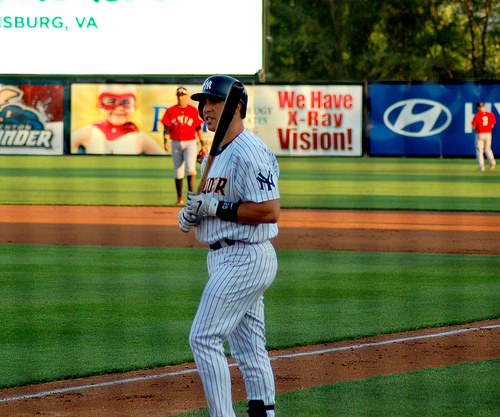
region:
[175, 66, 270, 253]
wooden base ball bat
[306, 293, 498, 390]
white lines painted on baseball field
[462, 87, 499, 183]
outfielder in red uniform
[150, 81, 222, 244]
outfielder in red baseball uniform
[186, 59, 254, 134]
hard dark nlue safety batters helmet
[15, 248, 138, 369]
bright green infield grass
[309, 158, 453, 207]
bright green outfield grass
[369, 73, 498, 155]
blue and white advertising banners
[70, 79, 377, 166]
multicolored advertising banner in baby on it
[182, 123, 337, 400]
white baseball uniform with blue stripes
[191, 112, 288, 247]
man wears pinstriped shirt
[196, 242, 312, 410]
man wears pinstriped pants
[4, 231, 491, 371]
infield is dark green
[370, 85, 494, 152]
right wall is blue and white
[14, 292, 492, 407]
painted line on infield dirt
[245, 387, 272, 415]
man wears shin guard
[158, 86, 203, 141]
opposing infielder wears red shirt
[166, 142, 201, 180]
opposing infielder wears grey pants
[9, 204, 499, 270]
infield dirt is clay brown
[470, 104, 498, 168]
opposing outfielder is turned away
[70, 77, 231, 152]
The billboard sign with the little boy on it.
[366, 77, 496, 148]
The blue and white billboard sign.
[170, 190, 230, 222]
The gloves the batter is wearing.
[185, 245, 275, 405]
The pants the batter is wearing.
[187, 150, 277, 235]
The shirt the batter is wearing.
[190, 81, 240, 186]
The bat the batter is holding.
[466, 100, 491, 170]
The player in front of the blue and white billboard sign.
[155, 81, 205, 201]
The player in front of the billboard with the little boy on it.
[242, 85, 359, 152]
The billboard sign that has the word Vision on it.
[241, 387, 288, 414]
The ankle support on the batter's leg area.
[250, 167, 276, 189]
The New York Yankee sign on the batter's sleeve.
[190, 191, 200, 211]
The Nike emblem on the batter's glove.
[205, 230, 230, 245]
The belt on the batter's pants.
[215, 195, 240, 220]
The black sweatband onthe batter's wrist.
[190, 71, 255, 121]
The black helmet the batter is wearing.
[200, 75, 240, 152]
The tip of the black bat the batter is holding.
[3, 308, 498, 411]
The white line on the field.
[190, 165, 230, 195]
The gold and brown letters on the front of the batter's shirt.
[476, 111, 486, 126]
The number 3 on the player's shirt next to the blue sign.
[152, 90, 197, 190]
The player standing in the field facing the batter.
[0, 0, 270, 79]
white board in the background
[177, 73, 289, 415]
baseball player wearing white shirt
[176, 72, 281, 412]
baseball player holding black ball and bat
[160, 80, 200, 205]
baseball player wearing red shirt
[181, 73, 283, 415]
baseball player wearing white pants with stripes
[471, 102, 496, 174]
baseball player wearing white pants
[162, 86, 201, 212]
baseball player wearing long black socks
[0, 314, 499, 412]
white line on baseball field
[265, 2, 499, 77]
green trees behind posters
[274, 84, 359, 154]
red letters on white poster